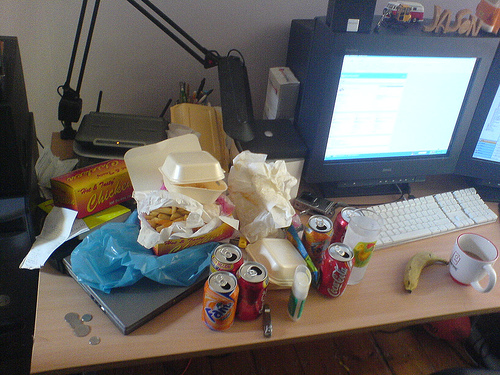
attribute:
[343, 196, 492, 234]
keyboard — white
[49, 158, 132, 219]
container — red, yellow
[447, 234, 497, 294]
mug — white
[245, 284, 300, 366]
clips — silver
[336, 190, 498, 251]
keyboard — white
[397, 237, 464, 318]
banana — yellow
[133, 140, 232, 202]
container — white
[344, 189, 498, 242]
keyboard — white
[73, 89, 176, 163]
router — wireless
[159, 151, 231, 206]
tray — slightly open, styrofoam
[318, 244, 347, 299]
can — open, coca cola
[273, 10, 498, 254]
monitor — computer, screen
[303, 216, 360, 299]
soda cans — open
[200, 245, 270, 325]
soda cans — open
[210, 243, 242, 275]
can — opened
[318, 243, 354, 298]
can — opened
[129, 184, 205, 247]
paper — white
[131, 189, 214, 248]
paper — white